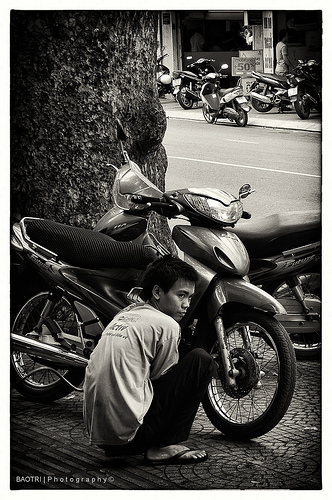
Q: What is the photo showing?
A: It is showing a sidewalk.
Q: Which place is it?
A: It is a sidewalk.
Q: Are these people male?
A: No, they are both male and female.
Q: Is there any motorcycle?
A: Yes, there are motorcycles.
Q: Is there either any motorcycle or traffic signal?
A: Yes, there are motorcycles.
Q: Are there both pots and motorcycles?
A: No, there are motorcycles but no pots.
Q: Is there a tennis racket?
A: No, there are no rackets.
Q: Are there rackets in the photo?
A: No, there are no rackets.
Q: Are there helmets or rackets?
A: No, there are no rackets or helmets.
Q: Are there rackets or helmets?
A: No, there are no rackets or helmets.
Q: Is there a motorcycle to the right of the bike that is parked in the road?
A: Yes, there are motorcycles to the right of the bike.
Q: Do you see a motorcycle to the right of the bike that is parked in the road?
A: Yes, there are motorcycles to the right of the bike.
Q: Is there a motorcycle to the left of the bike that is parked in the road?
A: No, the motorcycles are to the right of the bike.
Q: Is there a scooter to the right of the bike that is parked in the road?
A: No, there are motorcycles to the right of the bike.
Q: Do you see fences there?
A: No, there are no fences.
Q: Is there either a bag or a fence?
A: No, there are no fences or bags.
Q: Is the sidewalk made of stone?
A: Yes, the sidewalk is made of stone.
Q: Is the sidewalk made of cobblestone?
A: No, the sidewalk is made of stone.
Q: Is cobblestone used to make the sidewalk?
A: No, the sidewalk is made of stone.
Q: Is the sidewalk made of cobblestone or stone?
A: The sidewalk is made of stone.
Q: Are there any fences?
A: No, there are no fences.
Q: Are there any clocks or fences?
A: No, there are no fences or clocks.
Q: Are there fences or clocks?
A: No, there are no fences or clocks.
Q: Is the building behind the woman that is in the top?
A: Yes, the building is behind the woman.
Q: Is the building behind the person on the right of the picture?
A: Yes, the building is behind the woman.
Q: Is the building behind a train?
A: No, the building is behind the woman.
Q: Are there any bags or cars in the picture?
A: No, there are no cars or bags.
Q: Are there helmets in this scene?
A: No, there are no helmets.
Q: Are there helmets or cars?
A: No, there are no helmets or cars.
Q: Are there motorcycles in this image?
A: Yes, there are motorcycles.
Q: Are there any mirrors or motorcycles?
A: Yes, there are motorcycles.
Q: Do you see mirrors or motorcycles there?
A: Yes, there are motorcycles.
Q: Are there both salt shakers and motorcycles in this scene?
A: No, there are motorcycles but no salt shakers.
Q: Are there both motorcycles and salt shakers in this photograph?
A: No, there are motorcycles but no salt shakers.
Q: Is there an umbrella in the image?
A: No, there are no umbrellas.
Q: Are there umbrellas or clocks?
A: No, there are no umbrellas or clocks.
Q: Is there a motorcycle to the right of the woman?
A: Yes, there are motorcycles to the right of the woman.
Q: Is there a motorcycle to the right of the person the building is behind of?
A: Yes, there are motorcycles to the right of the woman.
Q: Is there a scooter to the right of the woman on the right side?
A: No, there are motorcycles to the right of the woman.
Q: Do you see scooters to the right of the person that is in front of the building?
A: No, there are motorcycles to the right of the woman.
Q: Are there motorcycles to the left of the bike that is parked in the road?
A: No, the motorcycles are to the right of the bike.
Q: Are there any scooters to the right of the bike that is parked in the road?
A: No, there are motorcycles to the right of the bike.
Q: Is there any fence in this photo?
A: No, there are no fences.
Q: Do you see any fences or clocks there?
A: No, there are no fences or clocks.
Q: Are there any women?
A: Yes, there is a woman.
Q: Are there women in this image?
A: Yes, there is a woman.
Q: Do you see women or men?
A: Yes, there is a woman.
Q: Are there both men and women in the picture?
A: Yes, there are both a woman and men.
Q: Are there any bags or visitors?
A: No, there are no bags or visitors.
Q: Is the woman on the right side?
A: Yes, the woman is on the right of the image.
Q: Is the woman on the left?
A: No, the woman is on the right of the image.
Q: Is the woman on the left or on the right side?
A: The woman is on the right of the image.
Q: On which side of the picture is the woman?
A: The woman is on the right of the image.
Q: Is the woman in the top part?
A: Yes, the woman is in the top of the image.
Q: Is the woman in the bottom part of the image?
A: No, the woman is in the top of the image.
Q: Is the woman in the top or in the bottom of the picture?
A: The woman is in the top of the image.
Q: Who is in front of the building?
A: The woman is in front of the building.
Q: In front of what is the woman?
A: The woman is in front of the building.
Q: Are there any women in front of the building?
A: Yes, there is a woman in front of the building.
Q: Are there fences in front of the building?
A: No, there is a woman in front of the building.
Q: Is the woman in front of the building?
A: Yes, the woman is in front of the building.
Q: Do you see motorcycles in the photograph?
A: Yes, there are motorcycles.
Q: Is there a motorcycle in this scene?
A: Yes, there are motorcycles.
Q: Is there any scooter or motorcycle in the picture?
A: Yes, there are motorcycles.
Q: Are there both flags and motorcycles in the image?
A: No, there are motorcycles but no flags.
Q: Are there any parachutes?
A: No, there are no parachutes.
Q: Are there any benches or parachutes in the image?
A: No, there are no parachutes or benches.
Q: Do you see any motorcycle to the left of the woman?
A: Yes, there are motorcycles to the left of the woman.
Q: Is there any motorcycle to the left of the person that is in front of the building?
A: Yes, there are motorcycles to the left of the woman.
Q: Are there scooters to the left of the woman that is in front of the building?
A: No, there are motorcycles to the left of the woman.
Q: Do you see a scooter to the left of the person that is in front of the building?
A: No, there are motorcycles to the left of the woman.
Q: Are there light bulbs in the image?
A: No, there are no light bulbs.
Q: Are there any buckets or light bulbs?
A: No, there are no light bulbs or buckets.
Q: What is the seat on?
A: The seat is on the motorcycle.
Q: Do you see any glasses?
A: No, there are no glasses.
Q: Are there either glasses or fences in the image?
A: No, there are no glasses or fences.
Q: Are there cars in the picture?
A: No, there are no cars.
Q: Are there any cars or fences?
A: No, there are no cars or fences.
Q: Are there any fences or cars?
A: No, there are no cars or fences.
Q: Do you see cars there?
A: No, there are no cars.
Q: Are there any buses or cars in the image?
A: No, there are no cars or buses.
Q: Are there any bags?
A: No, there are no bags.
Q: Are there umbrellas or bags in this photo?
A: No, there are no bags or umbrellas.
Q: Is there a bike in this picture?
A: Yes, there is a bike.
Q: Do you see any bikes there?
A: Yes, there is a bike.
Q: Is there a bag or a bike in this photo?
A: Yes, there is a bike.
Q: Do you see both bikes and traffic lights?
A: No, there is a bike but no traffic lights.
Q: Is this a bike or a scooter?
A: This is a bike.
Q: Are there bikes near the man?
A: Yes, there is a bike near the man.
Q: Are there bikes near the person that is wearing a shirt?
A: Yes, there is a bike near the man.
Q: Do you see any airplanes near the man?
A: No, there is a bike near the man.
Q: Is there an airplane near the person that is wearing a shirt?
A: No, there is a bike near the man.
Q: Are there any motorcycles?
A: Yes, there is a motorcycle.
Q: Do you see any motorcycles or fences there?
A: Yes, there is a motorcycle.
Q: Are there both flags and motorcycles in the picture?
A: No, there is a motorcycle but no flags.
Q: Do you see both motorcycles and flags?
A: No, there is a motorcycle but no flags.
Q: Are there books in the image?
A: No, there are no books.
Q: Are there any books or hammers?
A: No, there are no books or hammers.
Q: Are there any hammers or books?
A: No, there are no books or hammers.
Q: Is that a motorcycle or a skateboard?
A: That is a motorcycle.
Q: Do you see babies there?
A: No, there are no babies.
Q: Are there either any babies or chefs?
A: No, there are no babies or chefs.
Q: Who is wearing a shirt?
A: The man is wearing a shirt.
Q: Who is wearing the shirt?
A: The man is wearing a shirt.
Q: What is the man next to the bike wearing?
A: The man is wearing a shirt.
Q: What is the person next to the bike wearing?
A: The man is wearing a shirt.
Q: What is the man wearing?
A: The man is wearing a shirt.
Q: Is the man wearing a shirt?
A: Yes, the man is wearing a shirt.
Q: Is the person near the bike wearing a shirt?
A: Yes, the man is wearing a shirt.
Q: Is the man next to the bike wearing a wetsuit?
A: No, the man is wearing a shirt.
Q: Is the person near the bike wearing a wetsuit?
A: No, the man is wearing a shirt.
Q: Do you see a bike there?
A: Yes, there is a bike.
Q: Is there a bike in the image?
A: Yes, there is a bike.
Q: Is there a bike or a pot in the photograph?
A: Yes, there is a bike.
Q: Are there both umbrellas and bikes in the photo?
A: No, there is a bike but no umbrellas.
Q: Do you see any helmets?
A: No, there are no helmets.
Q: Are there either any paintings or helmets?
A: No, there are no helmets or paintings.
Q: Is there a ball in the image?
A: No, there are no balls.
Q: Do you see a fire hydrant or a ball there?
A: No, there are no balls or fire hydrants.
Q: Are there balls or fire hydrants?
A: No, there are no balls or fire hydrants.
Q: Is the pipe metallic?
A: Yes, the pipe is metallic.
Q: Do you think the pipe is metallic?
A: Yes, the pipe is metallic.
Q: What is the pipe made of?
A: The pipe is made of metal.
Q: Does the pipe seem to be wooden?
A: No, the pipe is metallic.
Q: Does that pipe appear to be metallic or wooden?
A: The pipe is metallic.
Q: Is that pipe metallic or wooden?
A: The pipe is metallic.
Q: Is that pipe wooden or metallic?
A: The pipe is metallic.